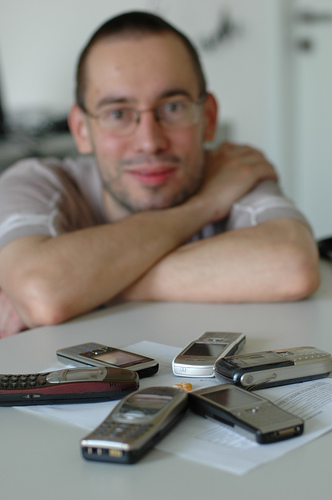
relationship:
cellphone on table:
[169, 325, 251, 380] [1, 250, 329, 497]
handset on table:
[0, 364, 140, 403] [1, 250, 329, 497]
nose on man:
[134, 127, 170, 156] [60, 62, 266, 294]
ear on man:
[198, 91, 223, 148] [2, 6, 321, 334]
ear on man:
[65, 106, 94, 157] [2, 6, 321, 334]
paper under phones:
[166, 405, 272, 498] [2, 315, 331, 476]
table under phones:
[10, 423, 60, 475] [0, 256, 330, 495]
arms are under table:
[0, 140, 321, 335] [1, 250, 329, 497]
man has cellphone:
[2, 6, 321, 334] [169, 325, 251, 380]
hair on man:
[76, 10, 205, 113] [0, 10, 320, 301]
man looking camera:
[2, 6, 321, 334] [2, 310, 317, 460]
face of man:
[88, 79, 202, 200] [0, 6, 322, 340]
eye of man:
[163, 100, 189, 117] [0, 6, 322, 340]